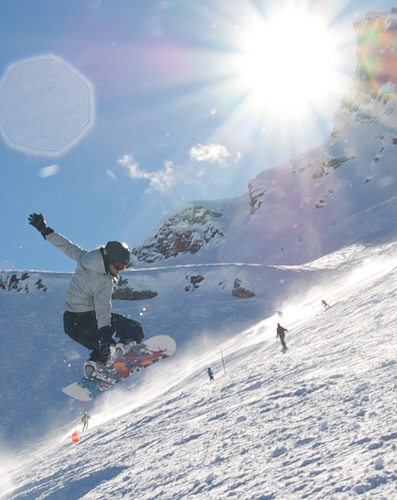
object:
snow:
[0, 75, 397, 499]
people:
[275, 323, 288, 350]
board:
[59, 332, 177, 406]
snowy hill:
[1, 267, 396, 496]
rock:
[313, 155, 328, 179]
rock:
[243, 175, 266, 215]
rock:
[132, 205, 225, 260]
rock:
[230, 276, 255, 298]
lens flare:
[0, 53, 96, 157]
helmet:
[102, 240, 131, 267]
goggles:
[111, 258, 129, 270]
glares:
[192, 0, 397, 164]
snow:
[4, 254, 391, 499]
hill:
[126, 0, 397, 264]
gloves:
[29, 204, 59, 241]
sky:
[14, 10, 396, 298]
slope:
[1, 232, 395, 497]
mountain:
[0, 6, 396, 465]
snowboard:
[61, 334, 176, 402]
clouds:
[100, 115, 255, 209]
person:
[29, 212, 144, 376]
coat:
[47, 227, 116, 327]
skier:
[206, 365, 215, 381]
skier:
[319, 298, 329, 309]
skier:
[79, 411, 90, 433]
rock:
[112, 278, 156, 303]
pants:
[62, 311, 145, 368]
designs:
[73, 345, 168, 396]